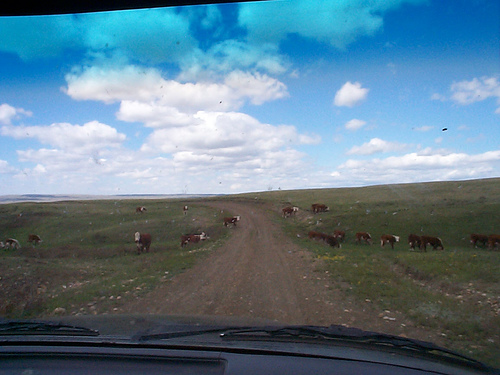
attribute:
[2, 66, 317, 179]
clouds — fluffy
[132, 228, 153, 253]
cow — white, brown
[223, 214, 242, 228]
cow — white, brown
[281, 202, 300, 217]
cow — white, brown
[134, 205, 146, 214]
cow — white, brown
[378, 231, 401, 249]
cow — white, brown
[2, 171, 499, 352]
field — open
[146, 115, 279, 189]
sky — cloudy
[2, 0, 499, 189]
sky — light blue, white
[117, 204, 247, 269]
cows — grazing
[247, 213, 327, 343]
road — brown